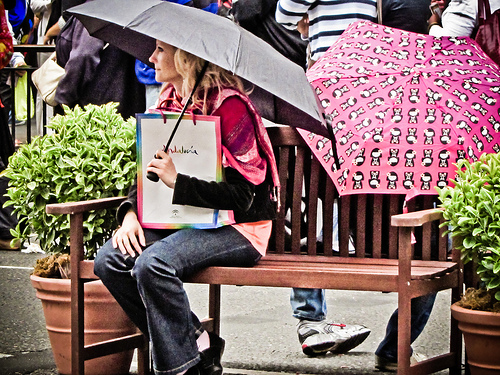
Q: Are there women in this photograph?
A: Yes, there is a woman.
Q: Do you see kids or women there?
A: Yes, there is a woman.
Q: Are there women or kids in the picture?
A: Yes, there is a woman.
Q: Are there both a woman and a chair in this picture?
A: No, there is a woman but no chairs.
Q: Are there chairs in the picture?
A: No, there are no chairs.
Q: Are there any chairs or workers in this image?
A: No, there are no chairs or workers.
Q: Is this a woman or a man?
A: This is a woman.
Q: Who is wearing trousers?
A: The woman is wearing trousers.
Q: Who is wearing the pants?
A: The woman is wearing trousers.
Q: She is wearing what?
A: The woman is wearing pants.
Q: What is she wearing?
A: The woman is wearing pants.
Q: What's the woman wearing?
A: The woman is wearing pants.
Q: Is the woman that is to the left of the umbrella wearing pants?
A: Yes, the woman is wearing pants.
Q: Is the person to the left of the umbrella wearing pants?
A: Yes, the woman is wearing pants.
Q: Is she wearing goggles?
A: No, the woman is wearing pants.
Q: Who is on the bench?
A: The woman is on the bench.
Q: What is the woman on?
A: The woman is on the bench.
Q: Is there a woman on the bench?
A: Yes, there is a woman on the bench.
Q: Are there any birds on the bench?
A: No, there is a woman on the bench.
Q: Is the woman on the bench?
A: Yes, the woman is on the bench.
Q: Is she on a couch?
A: No, the woman is on the bench.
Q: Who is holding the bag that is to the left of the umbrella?
A: The woman is holding the bag.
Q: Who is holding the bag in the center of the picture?
A: The woman is holding the bag.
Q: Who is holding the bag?
A: The woman is holding the bag.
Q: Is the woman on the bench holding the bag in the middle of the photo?
A: Yes, the woman is holding the bag.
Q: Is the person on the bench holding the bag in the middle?
A: Yes, the woman is holding the bag.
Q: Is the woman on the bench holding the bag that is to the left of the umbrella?
A: Yes, the woman is holding the bag.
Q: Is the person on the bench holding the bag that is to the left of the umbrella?
A: Yes, the woman is holding the bag.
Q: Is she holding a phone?
A: No, the woman is holding the bag.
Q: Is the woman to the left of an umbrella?
A: Yes, the woman is to the left of an umbrella.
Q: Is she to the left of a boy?
A: No, the woman is to the left of an umbrella.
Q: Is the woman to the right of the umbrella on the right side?
A: No, the woman is to the left of the umbrella.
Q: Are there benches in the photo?
A: Yes, there is a bench.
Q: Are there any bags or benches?
A: Yes, there is a bench.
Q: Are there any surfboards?
A: No, there are no surfboards.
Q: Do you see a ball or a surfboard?
A: No, there are no surfboards or balls.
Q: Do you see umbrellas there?
A: Yes, there is an umbrella.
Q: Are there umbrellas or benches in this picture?
A: Yes, there is an umbrella.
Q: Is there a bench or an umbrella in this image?
A: Yes, there is an umbrella.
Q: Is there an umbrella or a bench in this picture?
A: Yes, there is an umbrella.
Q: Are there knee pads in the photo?
A: No, there are no knee pads.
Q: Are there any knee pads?
A: No, there are no knee pads.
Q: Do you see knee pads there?
A: No, there are no knee pads.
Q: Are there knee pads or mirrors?
A: No, there are no knee pads or mirrors.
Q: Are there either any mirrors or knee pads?
A: No, there are no knee pads or mirrors.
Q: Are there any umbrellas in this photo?
A: Yes, there is an umbrella.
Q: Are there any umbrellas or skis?
A: Yes, there is an umbrella.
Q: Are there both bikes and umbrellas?
A: No, there is an umbrella but no bikes.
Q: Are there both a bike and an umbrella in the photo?
A: No, there is an umbrella but no bikes.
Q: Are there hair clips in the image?
A: No, there are no hair clips.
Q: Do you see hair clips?
A: No, there are no hair clips.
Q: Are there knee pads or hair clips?
A: No, there are no hair clips or knee pads.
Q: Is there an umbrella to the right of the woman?
A: Yes, there is an umbrella to the right of the woman.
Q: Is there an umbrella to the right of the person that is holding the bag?
A: Yes, there is an umbrella to the right of the woman.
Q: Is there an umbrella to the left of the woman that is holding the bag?
A: No, the umbrella is to the right of the woman.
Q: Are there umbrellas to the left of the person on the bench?
A: No, the umbrella is to the right of the woman.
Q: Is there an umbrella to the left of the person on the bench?
A: No, the umbrella is to the right of the woman.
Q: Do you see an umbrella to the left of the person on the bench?
A: No, the umbrella is to the right of the woman.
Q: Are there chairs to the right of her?
A: No, there is an umbrella to the right of the woman.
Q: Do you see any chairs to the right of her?
A: No, there is an umbrella to the right of the woman.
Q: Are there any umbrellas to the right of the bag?
A: Yes, there is an umbrella to the right of the bag.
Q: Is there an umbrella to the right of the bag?
A: Yes, there is an umbrella to the right of the bag.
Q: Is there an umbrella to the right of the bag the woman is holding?
A: Yes, there is an umbrella to the right of the bag.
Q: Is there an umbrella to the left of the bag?
A: No, the umbrella is to the right of the bag.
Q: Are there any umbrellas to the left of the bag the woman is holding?
A: No, the umbrella is to the right of the bag.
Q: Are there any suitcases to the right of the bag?
A: No, there is an umbrella to the right of the bag.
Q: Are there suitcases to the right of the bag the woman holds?
A: No, there is an umbrella to the right of the bag.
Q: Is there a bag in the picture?
A: Yes, there is a bag.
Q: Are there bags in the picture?
A: Yes, there is a bag.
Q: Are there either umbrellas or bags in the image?
A: Yes, there is a bag.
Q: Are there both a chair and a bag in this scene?
A: No, there is a bag but no chairs.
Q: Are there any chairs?
A: No, there are no chairs.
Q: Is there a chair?
A: No, there are no chairs.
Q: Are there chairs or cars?
A: No, there are no chairs or cars.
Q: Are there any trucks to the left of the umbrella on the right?
A: No, there is a bag to the left of the umbrella.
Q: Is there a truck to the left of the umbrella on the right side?
A: No, there is a bag to the left of the umbrella.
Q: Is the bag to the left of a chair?
A: No, the bag is to the left of the umbrella.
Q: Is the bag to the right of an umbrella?
A: No, the bag is to the left of an umbrella.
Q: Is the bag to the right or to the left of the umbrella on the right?
A: The bag is to the left of the umbrella.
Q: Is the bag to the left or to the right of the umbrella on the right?
A: The bag is to the left of the umbrella.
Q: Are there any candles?
A: No, there are no candles.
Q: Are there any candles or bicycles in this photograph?
A: No, there are no candles or bicycles.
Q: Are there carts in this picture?
A: No, there are no carts.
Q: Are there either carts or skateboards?
A: No, there are no carts or skateboards.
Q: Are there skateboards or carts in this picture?
A: No, there are no carts or skateboards.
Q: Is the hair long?
A: Yes, the hair is long.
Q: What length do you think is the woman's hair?
A: The hair is long.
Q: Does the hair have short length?
A: No, the hair is long.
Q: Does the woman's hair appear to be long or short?
A: The hair is long.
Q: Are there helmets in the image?
A: No, there are no helmets.